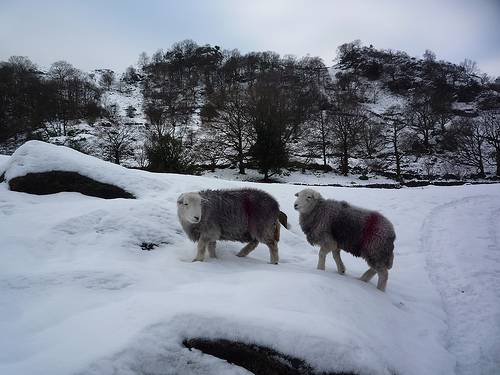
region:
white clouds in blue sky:
[14, 2, 74, 42]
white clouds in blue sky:
[43, 9, 84, 61]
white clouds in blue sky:
[81, 13, 123, 53]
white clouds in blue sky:
[130, 13, 166, 36]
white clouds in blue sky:
[171, 10, 213, 30]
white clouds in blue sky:
[241, 13, 274, 45]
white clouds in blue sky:
[288, 7, 310, 44]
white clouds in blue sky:
[338, 6, 395, 38]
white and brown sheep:
[175, 173, 287, 270]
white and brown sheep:
[289, 190, 403, 273]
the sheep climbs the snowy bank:
[288, 182, 396, 294]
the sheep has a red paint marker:
[292, 184, 398, 295]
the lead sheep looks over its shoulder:
[168, 181, 295, 264]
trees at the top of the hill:
[3, 35, 489, 168]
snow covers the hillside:
[1, 139, 496, 368]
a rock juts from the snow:
[6, 135, 148, 207]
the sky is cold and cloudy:
[8, 3, 492, 89]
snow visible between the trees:
[35, 85, 149, 165]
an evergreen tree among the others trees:
[246, 108, 291, 181]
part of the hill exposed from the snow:
[171, 330, 317, 373]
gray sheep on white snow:
[170, 185, 395, 295]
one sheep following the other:
[172, 181, 397, 283]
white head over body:
[175, 185, 205, 225]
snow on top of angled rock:
[2, 136, 138, 223]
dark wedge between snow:
[185, 330, 315, 370]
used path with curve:
[417, 186, 492, 367]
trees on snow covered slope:
[2, 65, 497, 185]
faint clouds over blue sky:
[0, 1, 492, 91]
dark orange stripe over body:
[347, 205, 382, 255]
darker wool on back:
[230, 180, 280, 221]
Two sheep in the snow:
[160, 170, 401, 275]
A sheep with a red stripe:
[291, 181, 421, 262]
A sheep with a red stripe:
[175, 180, 285, 250]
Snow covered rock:
[6, 131, 151, 226]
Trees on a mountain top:
[312, 37, 489, 109]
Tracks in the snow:
[415, 190, 475, 355]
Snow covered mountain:
[95, 60, 215, 145]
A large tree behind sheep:
[200, 55, 340, 155]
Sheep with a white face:
[170, 185, 200, 220]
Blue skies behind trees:
[140, 6, 313, 42]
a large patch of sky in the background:
[0, 0, 499, 85]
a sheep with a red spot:
[292, 188, 396, 293]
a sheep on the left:
[175, 187, 280, 265]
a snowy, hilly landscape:
[0, 139, 499, 374]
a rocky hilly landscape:
[0, 55, 499, 185]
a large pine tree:
[245, 115, 289, 181]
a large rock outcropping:
[0, 139, 170, 199]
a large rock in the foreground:
[34, 270, 414, 373]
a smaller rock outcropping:
[37, 199, 182, 256]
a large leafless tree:
[370, 103, 417, 180]